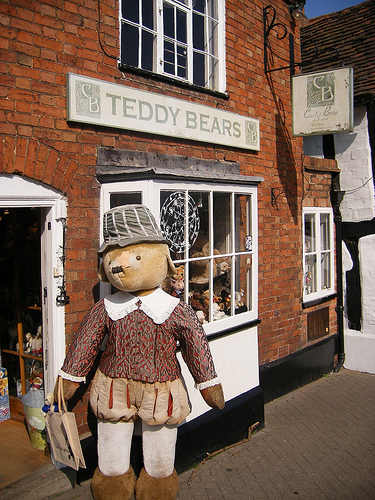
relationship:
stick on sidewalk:
[187, 420, 260, 486] [77, 367, 373, 496]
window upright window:
[160, 187, 253, 323] [119, 0, 227, 95]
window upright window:
[299, 208, 338, 300] [119, 0, 227, 95]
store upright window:
[1, 0, 345, 494] [119, 0, 227, 95]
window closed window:
[160, 187, 253, 323] [119, 0, 227, 95]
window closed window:
[299, 208, 338, 300] [119, 0, 227, 95]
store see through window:
[1, 0, 345, 494] [119, 0, 227, 95]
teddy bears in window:
[161, 238, 248, 331] [99, 172, 264, 340]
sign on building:
[64, 70, 259, 150] [0, 0, 347, 491]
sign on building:
[261, 4, 352, 136] [0, 0, 347, 491]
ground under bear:
[223, 454, 282, 496] [86, 228, 203, 424]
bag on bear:
[44, 373, 86, 471] [56, 207, 223, 496]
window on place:
[160, 187, 253, 323] [1, 1, 336, 498]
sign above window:
[64, 70, 259, 150] [160, 187, 253, 323]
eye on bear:
[132, 249, 145, 265] [84, 183, 209, 372]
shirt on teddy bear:
[57, 285, 220, 390] [54, 203, 224, 498]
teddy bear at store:
[63, 193, 236, 498] [1, 0, 345, 494]